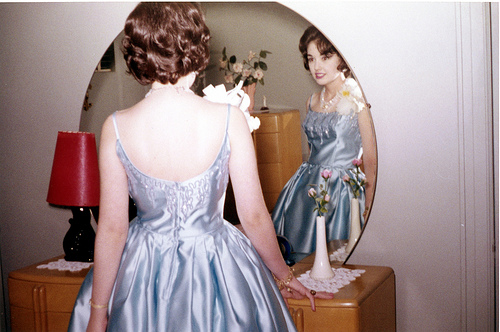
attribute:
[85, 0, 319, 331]
woman — dressed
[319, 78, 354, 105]
necklace — diamond, elegant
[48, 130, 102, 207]
lamp shade — red, dark red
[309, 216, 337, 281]
vase — white, tall, light pink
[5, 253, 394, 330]
dresser — brown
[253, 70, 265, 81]
flower — pink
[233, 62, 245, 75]
flower — pink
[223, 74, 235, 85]
flower — pink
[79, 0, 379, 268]
mirror — large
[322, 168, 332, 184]
flower — pink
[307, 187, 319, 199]
flower — pink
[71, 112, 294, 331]
dress — cinderella-style, old-fashioned, elegant, blue, long, silver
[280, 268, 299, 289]
bracelet — gold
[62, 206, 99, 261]
lamp base — black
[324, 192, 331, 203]
rose bud — pink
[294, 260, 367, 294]
doily — light pink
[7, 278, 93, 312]
dresser drawer — brown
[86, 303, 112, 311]
ribbon — gold